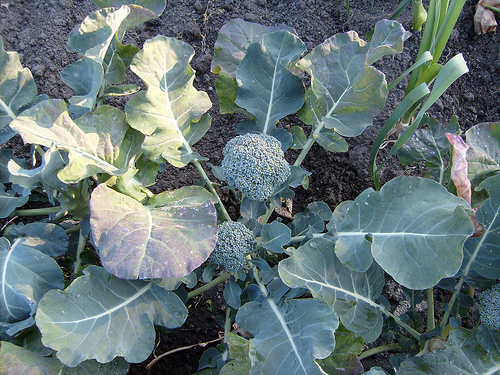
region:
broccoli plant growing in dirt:
[5, 8, 475, 361]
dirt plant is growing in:
[3, 7, 460, 132]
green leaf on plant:
[127, 38, 219, 165]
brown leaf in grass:
[447, 130, 477, 203]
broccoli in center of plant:
[219, 135, 291, 201]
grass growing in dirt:
[392, 3, 443, 163]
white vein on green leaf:
[52, 287, 172, 327]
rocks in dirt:
[196, 291, 223, 325]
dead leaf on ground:
[473, 6, 496, 32]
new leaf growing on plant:
[256, 223, 298, 253]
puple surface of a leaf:
[106, 209, 192, 265]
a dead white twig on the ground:
[138, 325, 246, 365]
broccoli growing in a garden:
[188, 116, 394, 343]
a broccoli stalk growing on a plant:
[211, 130, 294, 207]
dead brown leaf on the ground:
[466, 0, 496, 42]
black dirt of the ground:
[308, 158, 358, 190]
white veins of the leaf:
[272, 305, 311, 370]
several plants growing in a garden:
[2, 107, 456, 347]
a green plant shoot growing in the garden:
[390, 3, 447, 160]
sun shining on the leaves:
[19, 36, 214, 192]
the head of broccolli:
[221, 130, 290, 200]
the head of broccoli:
[212, 222, 254, 277]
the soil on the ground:
[1, 0, 497, 373]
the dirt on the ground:
[0, 0, 498, 371]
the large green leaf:
[302, 175, 472, 289]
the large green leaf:
[296, 18, 411, 174]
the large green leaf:
[234, 30, 306, 150]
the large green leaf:
[124, 33, 212, 169]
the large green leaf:
[10, 98, 157, 194]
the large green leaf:
[33, 263, 188, 367]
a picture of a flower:
[35, 27, 440, 356]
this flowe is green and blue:
[194, 115, 287, 281]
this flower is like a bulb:
[207, 123, 298, 215]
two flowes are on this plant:
[200, 126, 298, 281]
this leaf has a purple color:
[82, 179, 228, 281]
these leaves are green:
[302, 189, 480, 349]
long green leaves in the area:
[400, 5, 458, 176]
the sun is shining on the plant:
[25, 31, 213, 214]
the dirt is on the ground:
[17, 11, 474, 137]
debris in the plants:
[427, 127, 489, 238]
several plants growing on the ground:
[13, 18, 482, 371]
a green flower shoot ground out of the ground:
[411, 0, 461, 164]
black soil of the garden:
[306, 148, 366, 210]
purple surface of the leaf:
[94, 188, 204, 278]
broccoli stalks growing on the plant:
[212, 121, 292, 206]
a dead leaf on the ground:
[466, 0, 498, 52]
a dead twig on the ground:
[130, 325, 237, 367]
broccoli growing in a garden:
[196, 124, 307, 299]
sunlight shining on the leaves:
[6, 14, 228, 199]